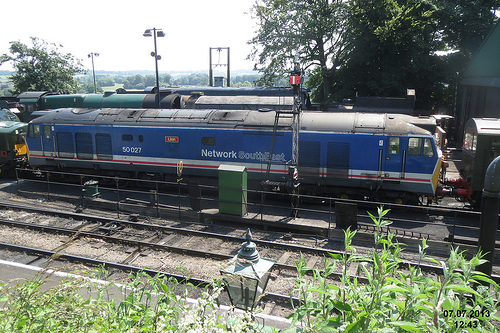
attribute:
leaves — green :
[332, 268, 475, 313]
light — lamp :
[129, 22, 181, 72]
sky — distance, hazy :
[9, 4, 399, 83]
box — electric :
[215, 162, 254, 220]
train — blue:
[15, 47, 469, 221]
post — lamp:
[143, 28, 171, 78]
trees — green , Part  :
[19, 2, 452, 100]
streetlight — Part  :
[85, 25, 178, 82]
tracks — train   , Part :
[9, 185, 462, 313]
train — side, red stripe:
[4, 71, 481, 253]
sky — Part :
[19, 1, 281, 83]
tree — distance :
[6, 10, 463, 100]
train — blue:
[13, 52, 484, 252]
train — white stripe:
[6, 88, 482, 262]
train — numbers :
[192, 139, 251, 162]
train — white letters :
[15, 61, 465, 239]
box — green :
[211, 163, 250, 223]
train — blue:
[33, 81, 484, 270]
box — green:
[200, 151, 260, 226]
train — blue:
[2, 78, 447, 203]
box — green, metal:
[217, 160, 249, 221]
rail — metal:
[1, 185, 481, 330]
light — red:
[284, 67, 307, 90]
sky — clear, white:
[2, 0, 485, 76]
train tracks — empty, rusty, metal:
[1, 178, 495, 325]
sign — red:
[155, 127, 184, 147]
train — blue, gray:
[2, 91, 465, 227]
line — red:
[22, 147, 432, 188]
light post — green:
[219, 234, 273, 330]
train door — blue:
[386, 134, 404, 184]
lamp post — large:
[141, 24, 173, 94]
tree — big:
[250, 0, 497, 136]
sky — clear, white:
[4, 5, 467, 95]